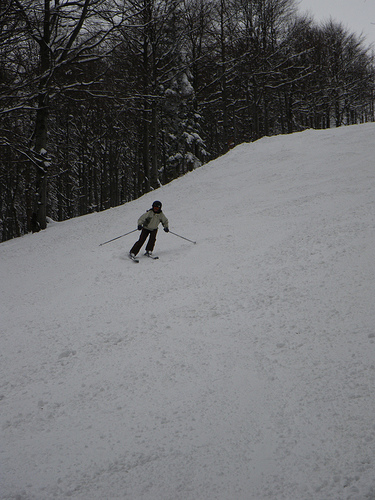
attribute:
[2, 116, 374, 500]
snow — white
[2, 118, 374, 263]
slope — white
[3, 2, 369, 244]
trees — bare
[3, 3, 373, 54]
sky — grey, hidden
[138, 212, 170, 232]
jacket — white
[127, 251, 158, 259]
feet — white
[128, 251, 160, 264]
skies — grey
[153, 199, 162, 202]
helmet — black